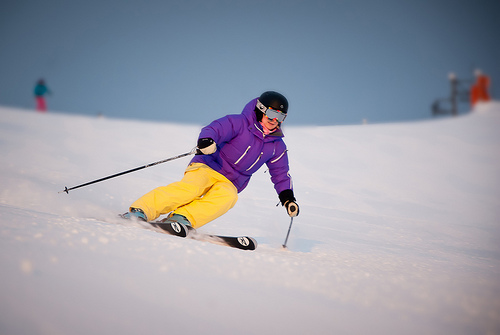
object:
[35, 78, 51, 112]
skier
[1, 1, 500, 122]
background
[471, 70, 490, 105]
skier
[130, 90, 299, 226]
person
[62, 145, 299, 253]
skiing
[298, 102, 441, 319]
slope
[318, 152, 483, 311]
snow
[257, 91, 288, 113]
helmet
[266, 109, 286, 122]
goggles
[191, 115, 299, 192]
coat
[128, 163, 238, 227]
pants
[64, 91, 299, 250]
leaning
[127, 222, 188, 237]
ski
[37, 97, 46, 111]
pants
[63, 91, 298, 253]
skier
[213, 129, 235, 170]
purple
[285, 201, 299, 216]
hand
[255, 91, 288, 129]
head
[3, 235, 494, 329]
ground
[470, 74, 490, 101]
pants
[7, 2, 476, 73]
sky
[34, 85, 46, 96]
coat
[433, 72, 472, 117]
lift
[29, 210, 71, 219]
prints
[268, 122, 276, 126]
smiling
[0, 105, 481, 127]
curve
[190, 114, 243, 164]
back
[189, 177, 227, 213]
yellow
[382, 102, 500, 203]
hill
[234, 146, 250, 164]
zippers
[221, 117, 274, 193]
front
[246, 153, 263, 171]
zippers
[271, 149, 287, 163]
zippers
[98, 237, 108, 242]
dots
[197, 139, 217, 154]
hands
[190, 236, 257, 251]
bottom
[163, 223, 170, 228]
black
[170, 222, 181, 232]
white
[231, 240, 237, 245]
black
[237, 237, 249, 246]
white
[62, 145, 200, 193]
ski pole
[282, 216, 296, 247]
ski pole